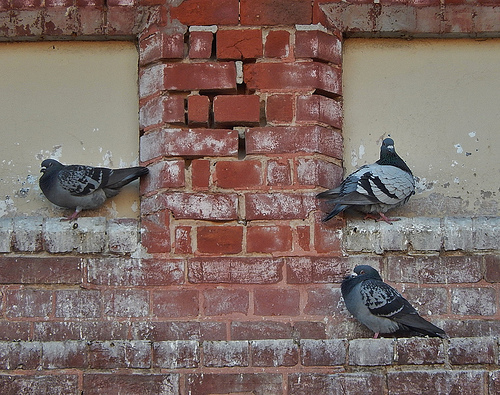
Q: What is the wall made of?
A: Red bricks.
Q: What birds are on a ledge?
A: Gray pigeons.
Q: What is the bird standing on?
A: Brick.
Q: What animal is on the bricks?
A: Piegeons.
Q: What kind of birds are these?
A: Pigeons.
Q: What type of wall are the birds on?
A: Brick.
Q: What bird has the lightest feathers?
A: The bird on the top right.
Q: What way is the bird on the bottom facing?
A: To the left.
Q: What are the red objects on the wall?
A: Bricks.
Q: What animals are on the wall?
A: Birds.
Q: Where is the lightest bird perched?
A: On the top right.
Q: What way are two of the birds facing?
A: To the left.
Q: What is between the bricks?
A: Mortar.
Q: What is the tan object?
A: Part of the wall.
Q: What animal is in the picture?
A: Birds.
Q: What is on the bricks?
A: Debris.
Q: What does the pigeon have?
A: Whitish grey feathers.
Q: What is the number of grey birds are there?
A: Three.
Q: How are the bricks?
A: Loose.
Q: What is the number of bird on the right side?
A: Two.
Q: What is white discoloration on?
A: The bricks.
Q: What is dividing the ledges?
A: Brick columns.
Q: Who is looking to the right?
A: Two birds.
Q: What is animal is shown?
A: Pidgeon.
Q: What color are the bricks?
A: Red.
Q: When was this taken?
A: Daytime.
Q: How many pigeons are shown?
A: 3.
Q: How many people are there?
A: 0.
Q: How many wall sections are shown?
A: 2.